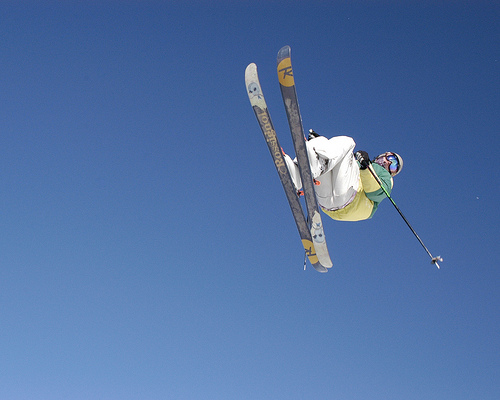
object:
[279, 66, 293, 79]
letter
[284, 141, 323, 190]
boot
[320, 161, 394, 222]
jacket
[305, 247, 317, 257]
r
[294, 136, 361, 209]
pants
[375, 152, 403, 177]
helmet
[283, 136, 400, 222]
alien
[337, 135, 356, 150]
knee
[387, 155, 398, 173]
goggles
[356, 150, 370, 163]
glove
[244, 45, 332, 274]
ski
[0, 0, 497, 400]
blue sky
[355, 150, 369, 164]
hand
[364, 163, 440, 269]
ski pole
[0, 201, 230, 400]
cloud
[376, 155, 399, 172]
face